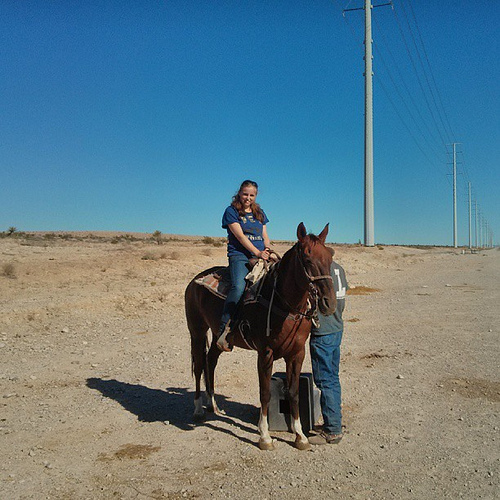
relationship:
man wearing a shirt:
[308, 247, 348, 445] [309, 260, 347, 335]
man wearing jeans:
[308, 247, 348, 445] [308, 332, 344, 433]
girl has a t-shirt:
[217, 181, 279, 349] [222, 205, 269, 254]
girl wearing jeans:
[217, 181, 279, 349] [223, 257, 267, 340]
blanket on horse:
[194, 270, 267, 303] [185, 222, 334, 451]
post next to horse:
[353, 1, 381, 241] [185, 222, 334, 451]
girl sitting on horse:
[217, 181, 279, 349] [185, 222, 334, 451]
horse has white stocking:
[185, 222, 334, 451] [205, 393, 219, 413]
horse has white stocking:
[185, 222, 334, 451] [194, 396, 205, 421]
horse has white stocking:
[185, 222, 334, 451] [291, 415, 309, 451]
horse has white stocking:
[185, 222, 334, 451] [260, 412, 276, 449]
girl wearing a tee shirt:
[217, 181, 279, 349] [222, 205, 269, 254]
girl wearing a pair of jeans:
[217, 181, 279, 349] [223, 257, 267, 340]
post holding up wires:
[341, 1, 394, 247] [370, 2, 463, 183]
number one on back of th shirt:
[334, 268, 346, 300] [309, 260, 347, 335]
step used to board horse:
[269, 371, 314, 433] [185, 222, 334, 451]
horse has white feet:
[185, 222, 334, 451] [291, 415, 309, 451]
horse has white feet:
[185, 222, 334, 451] [256, 410, 272, 450]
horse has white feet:
[185, 222, 334, 451] [206, 390, 223, 417]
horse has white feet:
[185, 222, 334, 451] [194, 396, 205, 421]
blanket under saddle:
[194, 270, 267, 303] [215, 250, 279, 281]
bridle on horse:
[291, 249, 334, 289] [185, 222, 334, 451]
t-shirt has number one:
[309, 260, 347, 335] [334, 268, 346, 300]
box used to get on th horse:
[269, 371, 314, 433] [185, 222, 334, 451]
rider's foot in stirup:
[218, 331, 231, 352] [217, 293, 253, 352]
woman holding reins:
[217, 181, 279, 349] [258, 252, 320, 324]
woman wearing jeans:
[217, 181, 279, 349] [223, 257, 267, 340]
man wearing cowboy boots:
[308, 247, 348, 445] [312, 432, 343, 443]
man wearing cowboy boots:
[308, 247, 348, 445] [315, 423, 327, 431]